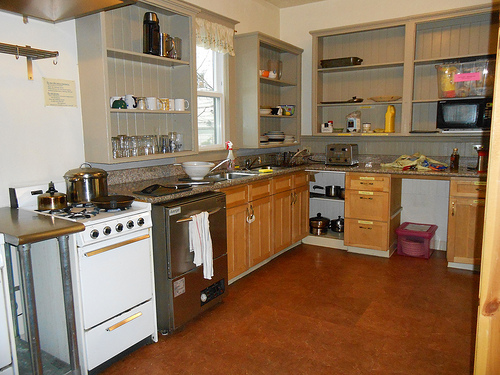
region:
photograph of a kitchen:
[7, 4, 489, 369]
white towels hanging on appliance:
[185, 207, 219, 274]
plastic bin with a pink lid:
[396, 215, 443, 260]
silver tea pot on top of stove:
[33, 177, 68, 210]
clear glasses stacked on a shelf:
[114, 118, 207, 160]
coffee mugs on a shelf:
[97, 79, 192, 120]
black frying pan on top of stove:
[76, 189, 138, 224]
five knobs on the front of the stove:
[84, 214, 149, 241]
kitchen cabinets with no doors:
[106, 0, 485, 160]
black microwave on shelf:
[432, 94, 490, 139]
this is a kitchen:
[38, 14, 483, 366]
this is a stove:
[25, 182, 177, 362]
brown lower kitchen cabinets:
[198, 156, 343, 276]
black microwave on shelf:
[420, 91, 488, 143]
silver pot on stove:
[55, 145, 120, 215]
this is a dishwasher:
[143, 187, 248, 329]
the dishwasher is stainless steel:
[145, 185, 268, 345]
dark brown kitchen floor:
[266, 250, 445, 363]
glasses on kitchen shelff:
[97, 112, 236, 181]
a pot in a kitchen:
[57, 169, 125, 216]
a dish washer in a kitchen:
[161, 152, 289, 314]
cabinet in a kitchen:
[219, 163, 336, 287]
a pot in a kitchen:
[305, 212, 338, 245]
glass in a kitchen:
[104, 116, 184, 158]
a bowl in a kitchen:
[181, 141, 239, 194]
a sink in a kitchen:
[194, 148, 254, 195]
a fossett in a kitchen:
[208, 130, 245, 183]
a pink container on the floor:
[371, 206, 461, 279]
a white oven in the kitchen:
[31, 183, 195, 371]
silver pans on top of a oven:
[12, 163, 143, 223]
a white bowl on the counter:
[152, 135, 227, 192]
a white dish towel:
[166, 197, 277, 317]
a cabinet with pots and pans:
[291, 161, 377, 271]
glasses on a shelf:
[76, 100, 223, 187]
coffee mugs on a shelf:
[96, 89, 228, 131]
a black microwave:
[421, 90, 498, 150]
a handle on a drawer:
[353, 184, 379, 205]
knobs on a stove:
[91, 223, 115, 240]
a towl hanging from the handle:
[181, 212, 220, 276]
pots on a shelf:
[309, 206, 338, 237]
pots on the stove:
[71, 158, 123, 218]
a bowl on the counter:
[182, 145, 217, 181]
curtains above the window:
[187, 18, 240, 50]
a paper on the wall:
[42, 70, 82, 115]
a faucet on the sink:
[213, 151, 238, 180]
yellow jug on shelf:
[383, 104, 393, 131]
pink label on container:
[450, 70, 484, 82]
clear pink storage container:
[396, 216, 439, 256]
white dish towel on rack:
[189, 209, 219, 280]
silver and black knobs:
[79, 219, 153, 234]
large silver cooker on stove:
[63, 159, 110, 201]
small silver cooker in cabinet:
[313, 183, 344, 197]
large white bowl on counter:
[173, 157, 213, 179]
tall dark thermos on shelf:
[144, 7, 162, 59]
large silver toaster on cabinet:
[326, 138, 365, 170]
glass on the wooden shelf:
[106, 135, 119, 158]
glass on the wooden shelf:
[125, 133, 135, 154]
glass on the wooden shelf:
[128, 130, 138, 156]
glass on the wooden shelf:
[135, 132, 145, 159]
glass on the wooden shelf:
[142, 130, 152, 158]